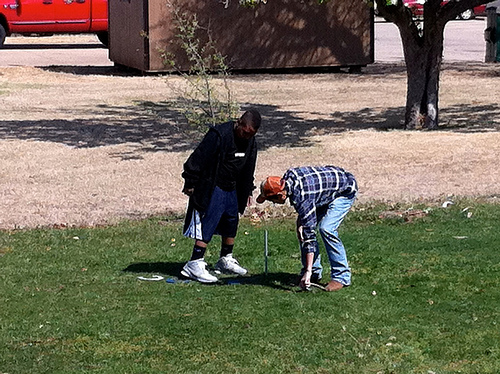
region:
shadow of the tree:
[55, 80, 180, 160]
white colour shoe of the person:
[179, 246, 244, 282]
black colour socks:
[183, 240, 246, 253]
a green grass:
[75, 295, 435, 353]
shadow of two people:
[127, 259, 287, 296]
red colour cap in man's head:
[255, 168, 288, 218]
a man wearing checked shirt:
[288, 163, 349, 207]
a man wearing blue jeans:
[322, 199, 354, 276]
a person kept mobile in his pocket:
[232, 148, 254, 164]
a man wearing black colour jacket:
[188, 119, 269, 210]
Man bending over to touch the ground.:
[260, 162, 360, 292]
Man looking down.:
[175, 105, 260, 285]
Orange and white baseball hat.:
[255, 171, 281, 201]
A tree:
[370, 0, 480, 130]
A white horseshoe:
[132, 265, 162, 285]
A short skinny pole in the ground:
[261, 225, 271, 276]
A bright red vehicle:
[0, 0, 115, 50]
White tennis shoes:
[176, 255, 246, 282]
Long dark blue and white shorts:
[180, 185, 236, 235]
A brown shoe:
[317, 275, 353, 288]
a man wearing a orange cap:
[248, 172, 292, 220]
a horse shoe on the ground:
[114, 269, 171, 296]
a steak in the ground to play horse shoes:
[255, 220, 282, 288]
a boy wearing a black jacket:
[172, 97, 269, 218]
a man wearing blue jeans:
[265, 150, 377, 314]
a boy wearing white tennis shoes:
[171, 93, 263, 309]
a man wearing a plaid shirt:
[258, 157, 366, 227]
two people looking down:
[179, 100, 400, 263]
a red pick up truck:
[0, 1, 120, 55]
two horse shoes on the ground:
[138, 266, 192, 293]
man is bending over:
[277, 159, 382, 307]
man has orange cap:
[268, 176, 299, 204]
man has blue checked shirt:
[288, 152, 350, 221]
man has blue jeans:
[332, 197, 362, 285]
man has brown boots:
[321, 271, 353, 293]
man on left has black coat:
[183, 112, 273, 192]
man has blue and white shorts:
[172, 185, 250, 223]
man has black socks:
[186, 243, 242, 263]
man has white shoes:
[152, 247, 249, 284]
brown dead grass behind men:
[30, 55, 293, 185]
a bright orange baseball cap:
[252, 172, 284, 199]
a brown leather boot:
[322, 277, 344, 294]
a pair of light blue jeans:
[305, 195, 354, 282]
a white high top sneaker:
[180, 257, 215, 285]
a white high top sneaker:
[217, 252, 246, 277]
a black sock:
[192, 245, 208, 260]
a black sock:
[221, 241, 236, 255]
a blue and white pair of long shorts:
[182, 185, 244, 235]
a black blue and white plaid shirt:
[285, 164, 355, 252]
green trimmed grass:
[1, 201, 498, 371]